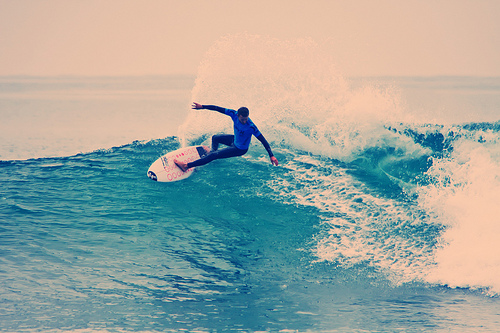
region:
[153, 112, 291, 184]
a man riding a surboard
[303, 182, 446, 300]
white ocean foam in front of a wave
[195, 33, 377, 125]
white ocean spray from the back of the surboard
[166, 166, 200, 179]
red lettering on the white surboard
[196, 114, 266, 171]
the man's blue wetsuit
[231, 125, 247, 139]
black lettering on the man's shirt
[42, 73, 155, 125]
calm blue waters behind the wave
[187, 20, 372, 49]
cloudy grey skies over the ocean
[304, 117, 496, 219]
a cresting wave rolling over on itself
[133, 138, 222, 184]
a surfboard on the ocean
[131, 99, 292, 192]
a man on a surfboard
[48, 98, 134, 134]
calm blue water behind the wave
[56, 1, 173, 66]
cloudy grey skies over the ocean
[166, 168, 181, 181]
red lettering on the white surboard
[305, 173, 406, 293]
white ocean foam in front of the wave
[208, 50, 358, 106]
white ocean spray coming off the back of the surfboard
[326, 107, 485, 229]
a cresting wave rolling over itself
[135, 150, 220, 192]
a white surfboard on the ocean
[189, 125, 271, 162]
the man's black and blue wetsuit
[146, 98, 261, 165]
man is on surfboard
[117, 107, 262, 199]
man on white surfboard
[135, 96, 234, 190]
pink rings on surfboard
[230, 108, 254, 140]
man has blue shirt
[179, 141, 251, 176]
man has black pants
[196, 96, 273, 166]
man's arms are extended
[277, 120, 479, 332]
white surf next to man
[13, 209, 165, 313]
crystal blue water in front of man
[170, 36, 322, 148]
man kicking up white spray with surfboard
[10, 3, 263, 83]
grey and pink sky behind man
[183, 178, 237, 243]
part of a water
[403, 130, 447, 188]
part of a splash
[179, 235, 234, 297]
part of a water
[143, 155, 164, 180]
edge of a board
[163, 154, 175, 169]
part of a board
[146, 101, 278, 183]
Male surfer catching wave in ocean.